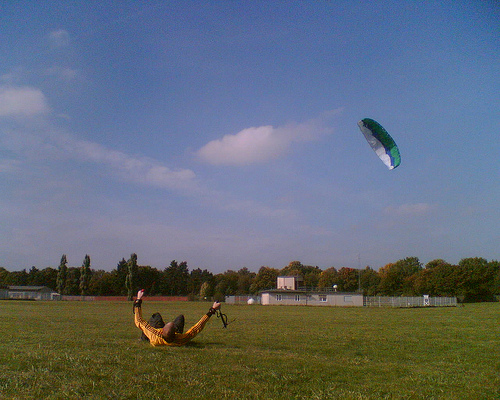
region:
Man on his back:
[133, 287, 221, 348]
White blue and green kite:
[356, 117, 401, 169]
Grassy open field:
[0, 297, 498, 397]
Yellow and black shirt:
[131, 305, 207, 345]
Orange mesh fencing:
[60, 295, 190, 302]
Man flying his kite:
[130, 116, 401, 348]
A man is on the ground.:
[126, 282, 240, 348]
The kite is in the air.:
[351, 115, 407, 180]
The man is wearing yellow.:
[123, 280, 236, 345]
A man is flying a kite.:
[121, 279, 234, 356]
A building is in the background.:
[222, 272, 464, 312]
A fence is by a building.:
[363, 294, 463, 310]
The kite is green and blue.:
[353, 114, 405, 175]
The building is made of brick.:
[257, 275, 367, 315]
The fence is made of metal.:
[361, 294, 459, 310]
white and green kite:
[359, 121, 400, 172]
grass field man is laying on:
[0, 299, 499, 399]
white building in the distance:
[260, 271, 365, 311]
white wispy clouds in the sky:
[7, 12, 432, 264]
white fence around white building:
[218, 289, 460, 310]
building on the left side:
[5, 284, 52, 301]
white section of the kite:
[351, 121, 393, 172]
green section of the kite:
[366, 114, 414, 166]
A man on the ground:
[133, 289, 219, 349]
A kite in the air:
[353, 116, 403, 172]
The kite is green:
[356, 117, 402, 170]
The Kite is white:
[356, 116, 401, 171]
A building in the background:
[261, 273, 366, 305]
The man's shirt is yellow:
[133, 301, 207, 348]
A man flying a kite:
[133, 117, 402, 347]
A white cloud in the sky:
[185, 108, 339, 166]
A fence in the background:
[226, 293, 458, 307]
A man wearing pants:
[141, 313, 185, 343]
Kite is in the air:
[349, 102, 417, 187]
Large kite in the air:
[353, 105, 416, 185]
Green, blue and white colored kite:
[348, 104, 422, 179]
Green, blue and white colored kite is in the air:
[350, 110, 416, 178]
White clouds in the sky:
[8, 74, 328, 209]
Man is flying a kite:
[92, 95, 420, 357]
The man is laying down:
[123, 281, 240, 350]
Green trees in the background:
[383, 253, 491, 298]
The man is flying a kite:
[343, 98, 445, 173]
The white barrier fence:
[368, 292, 463, 310]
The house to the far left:
[3, 280, 58, 305]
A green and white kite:
[350, 105, 407, 177]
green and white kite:
[353, 106, 405, 182]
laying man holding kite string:
[125, 279, 233, 351]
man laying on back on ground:
[125, 279, 234, 351]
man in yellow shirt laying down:
[128, 285, 231, 353]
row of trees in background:
[5, 251, 499, 308]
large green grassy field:
[4, 288, 498, 398]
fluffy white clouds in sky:
[4, 21, 453, 284]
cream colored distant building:
[257, 270, 369, 314]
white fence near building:
[360, 287, 461, 312]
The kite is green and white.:
[342, 95, 419, 192]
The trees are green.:
[397, 247, 477, 289]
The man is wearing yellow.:
[130, 305, 210, 358]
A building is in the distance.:
[262, 288, 353, 310]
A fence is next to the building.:
[370, 289, 455, 311]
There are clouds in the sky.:
[200, 93, 304, 178]